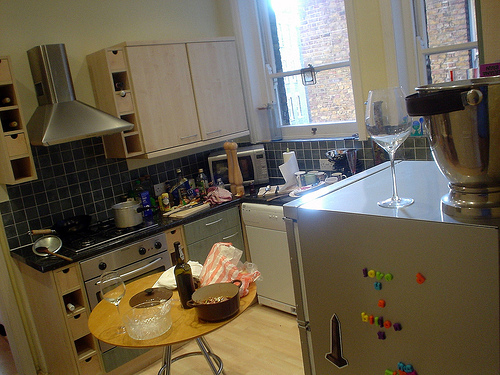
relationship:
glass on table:
[100, 271, 127, 334] [77, 260, 268, 373]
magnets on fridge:
[344, 250, 442, 373] [283, 159, 497, 375]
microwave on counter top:
[208, 145, 272, 185] [8, 183, 304, 274]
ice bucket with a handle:
[406, 71, 498, 223] [405, 88, 465, 114]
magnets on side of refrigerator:
[329, 277, 464, 365] [284, 161, 488, 355]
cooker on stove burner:
[111, 201, 156, 229] [106, 222, 155, 251]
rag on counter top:
[200, 183, 233, 204] [15, 183, 304, 274]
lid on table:
[186, 280, 243, 323] [77, 260, 268, 373]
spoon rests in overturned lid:
[35, 245, 71, 263] [181, 271, 251, 326]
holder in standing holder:
[279, 151, 300, 183] [275, 145, 300, 194]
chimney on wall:
[32, 93, 109, 133] [63, 32, 104, 104]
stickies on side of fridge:
[360, 262, 426, 372] [283, 159, 497, 375]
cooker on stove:
[109, 187, 159, 238] [55, 212, 182, 372]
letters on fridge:
[356, 262, 433, 372] [283, 151, 496, 372]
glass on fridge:
[362, 86, 412, 206] [283, 151, 496, 372]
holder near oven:
[279, 151, 300, 183] [77, 250, 186, 295]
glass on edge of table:
[98, 268, 130, 337] [85, 259, 256, 371]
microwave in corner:
[208, 144, 270, 190] [198, 130, 288, 202]